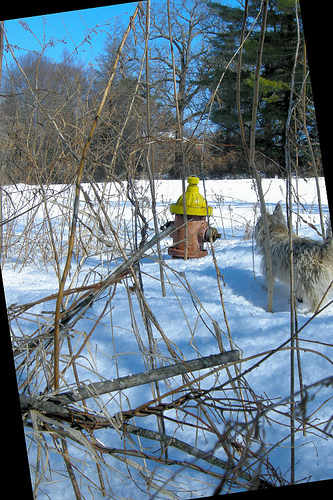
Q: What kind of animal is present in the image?
A: A small white dog.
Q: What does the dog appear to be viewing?
A: A fire hydrant.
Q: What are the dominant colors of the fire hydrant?
A: Red and yellow.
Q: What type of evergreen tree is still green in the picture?
A: A pine tree.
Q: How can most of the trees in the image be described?
A: Tall and leafless.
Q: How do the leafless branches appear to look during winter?
A: Dead.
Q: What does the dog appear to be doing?
A: Investigating the fire hydrant.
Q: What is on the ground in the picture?
A: Snow.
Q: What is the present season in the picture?
A: Winter.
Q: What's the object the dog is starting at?
A: Hydrant.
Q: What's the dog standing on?
A: Snow.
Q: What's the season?
A: Winter.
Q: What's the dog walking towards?
A: Hydrant.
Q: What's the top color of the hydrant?
A: Yellow.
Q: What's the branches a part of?
A: Tree.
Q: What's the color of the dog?
A: Blonde.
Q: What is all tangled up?
A: Twigs.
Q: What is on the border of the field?
A: Trees.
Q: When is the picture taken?
A: Winter.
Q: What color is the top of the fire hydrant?
A: Yellow.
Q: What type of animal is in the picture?
A: Dog.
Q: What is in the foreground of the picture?
A: Trees.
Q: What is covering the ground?
A: Snow.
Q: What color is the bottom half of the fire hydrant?
A: Red.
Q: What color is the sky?
A: Blue.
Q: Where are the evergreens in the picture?
A: Behind the dog.